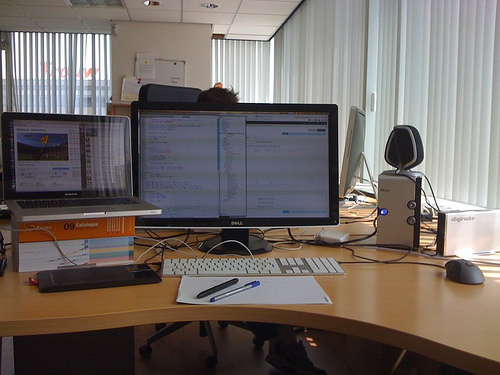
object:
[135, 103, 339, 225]
monitor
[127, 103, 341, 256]
computer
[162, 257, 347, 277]
keyboard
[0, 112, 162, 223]
computer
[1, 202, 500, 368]
table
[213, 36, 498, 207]
curtains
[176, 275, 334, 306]
paper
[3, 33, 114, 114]
blinds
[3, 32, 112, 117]
door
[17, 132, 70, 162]
video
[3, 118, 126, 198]
monitor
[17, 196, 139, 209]
keyboard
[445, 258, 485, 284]
mouse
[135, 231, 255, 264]
wires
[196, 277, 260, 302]
an ink pen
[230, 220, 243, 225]
dell logo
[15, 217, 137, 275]
books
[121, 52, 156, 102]
papers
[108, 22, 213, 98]
wall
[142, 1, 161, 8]
bulb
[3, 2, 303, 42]
ceiling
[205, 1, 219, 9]
bulb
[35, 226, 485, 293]
accessories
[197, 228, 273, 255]
stand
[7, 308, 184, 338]
edge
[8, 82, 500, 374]
work station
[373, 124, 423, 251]
computer speakers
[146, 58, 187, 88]
dry erase board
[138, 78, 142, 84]
colorful thumb tacks